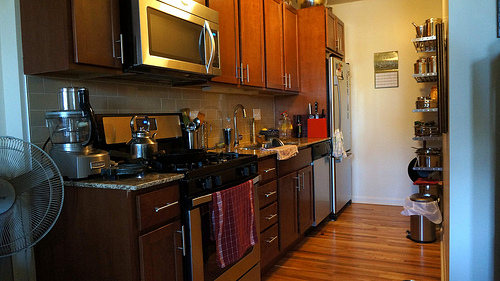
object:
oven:
[137, 146, 261, 281]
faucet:
[230, 103, 246, 146]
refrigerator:
[326, 55, 354, 220]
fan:
[0, 134, 69, 276]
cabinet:
[36, 180, 187, 276]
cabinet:
[208, 144, 280, 270]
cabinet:
[17, 0, 134, 80]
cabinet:
[206, 0, 241, 88]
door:
[239, 2, 264, 84]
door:
[262, 0, 284, 89]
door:
[281, 0, 301, 89]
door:
[206, 0, 239, 84]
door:
[296, 165, 314, 235]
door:
[275, 172, 300, 257]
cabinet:
[279, 166, 315, 255]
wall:
[345, 1, 444, 201]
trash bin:
[405, 190, 438, 241]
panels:
[286, 248, 442, 279]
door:
[67, 0, 126, 70]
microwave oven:
[127, 1, 238, 81]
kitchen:
[2, 0, 499, 281]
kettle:
[114, 105, 174, 169]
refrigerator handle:
[335, 81, 342, 123]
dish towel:
[209, 178, 257, 267]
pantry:
[406, 14, 447, 196]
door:
[324, 9, 336, 51]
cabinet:
[323, 9, 345, 56]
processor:
[44, 84, 131, 184]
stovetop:
[127, 136, 254, 178]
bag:
[399, 196, 442, 223]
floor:
[264, 198, 444, 281]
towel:
[330, 127, 349, 159]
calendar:
[373, 50, 399, 88]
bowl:
[44, 109, 93, 142]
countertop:
[35, 170, 186, 190]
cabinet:
[281, 2, 302, 90]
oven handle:
[186, 179, 264, 206]